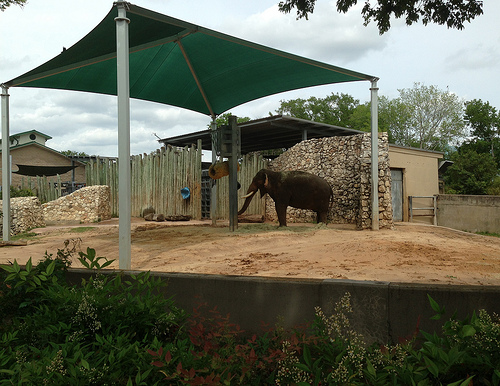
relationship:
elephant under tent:
[227, 170, 338, 227] [25, 10, 340, 138]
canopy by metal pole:
[1, 0, 378, 273] [0, 82, 11, 243]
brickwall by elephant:
[3, 261, 498, 373] [232, 158, 333, 230]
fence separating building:
[20, 140, 204, 221] [167, 102, 464, 242]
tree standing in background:
[208, 81, 500, 195] [106, 43, 495, 180]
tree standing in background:
[387, 77, 468, 156] [106, 43, 495, 180]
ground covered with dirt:
[1, 212, 496, 289] [0, 211, 497, 285]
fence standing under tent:
[11, 137, 202, 219] [1, 0, 376, 120]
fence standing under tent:
[215, 148, 267, 221] [1, 0, 376, 120]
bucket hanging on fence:
[181, 187, 191, 200] [20, 140, 204, 221]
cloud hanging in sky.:
[0, 0, 500, 159] [285, 13, 466, 80]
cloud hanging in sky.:
[438, 40, 485, 73] [285, 13, 466, 80]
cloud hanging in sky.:
[69, 110, 126, 127] [285, 13, 466, 80]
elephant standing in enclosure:
[238, 168, 334, 227] [1, 178, 484, 346]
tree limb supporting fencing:
[18, 138, 268, 221] [25, 137, 271, 231]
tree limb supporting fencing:
[191, 135, 202, 219] [25, 137, 271, 231]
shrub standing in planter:
[0, 235, 500, 386] [2, 266, 484, 382]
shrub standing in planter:
[310, 290, 384, 382] [2, 266, 484, 382]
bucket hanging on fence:
[169, 177, 199, 207] [65, 152, 220, 203]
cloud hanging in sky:
[0, 0, 500, 159] [0, 0, 499, 162]